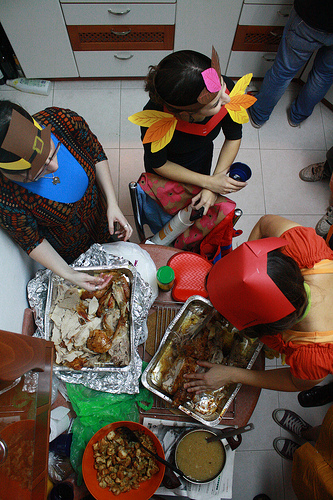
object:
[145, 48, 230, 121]
girl head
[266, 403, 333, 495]
person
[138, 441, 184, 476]
spoon handle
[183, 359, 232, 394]
hand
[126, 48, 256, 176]
costume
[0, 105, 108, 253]
costume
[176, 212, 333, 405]
person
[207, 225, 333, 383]
costume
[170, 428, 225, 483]
bowl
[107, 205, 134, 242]
hand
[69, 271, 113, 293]
hand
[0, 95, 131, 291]
person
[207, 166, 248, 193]
hand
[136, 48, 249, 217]
person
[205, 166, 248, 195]
right hand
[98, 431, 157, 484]
food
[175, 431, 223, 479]
gravy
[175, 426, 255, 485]
cooking pot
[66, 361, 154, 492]
plastic bag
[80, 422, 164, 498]
bowl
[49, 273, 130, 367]
turkey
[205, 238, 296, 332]
hat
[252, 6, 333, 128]
person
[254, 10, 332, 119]
blue jeans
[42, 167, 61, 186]
necklace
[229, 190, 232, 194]
ring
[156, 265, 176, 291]
container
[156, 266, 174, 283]
lid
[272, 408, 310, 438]
shoe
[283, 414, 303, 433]
laces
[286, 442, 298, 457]
laces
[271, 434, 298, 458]
shoe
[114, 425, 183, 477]
spoon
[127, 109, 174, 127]
leaf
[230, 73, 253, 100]
leaf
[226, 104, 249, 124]
leaf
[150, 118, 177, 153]
leaf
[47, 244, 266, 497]
table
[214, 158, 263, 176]
cup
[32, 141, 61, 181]
glasses